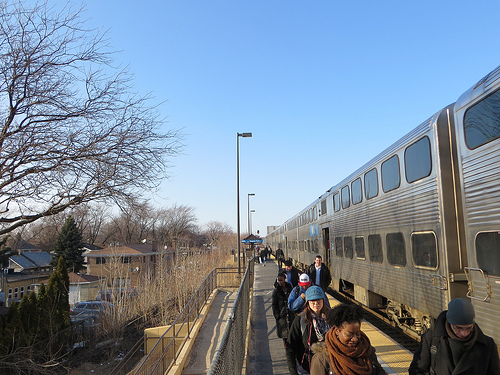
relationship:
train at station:
[254, 62, 498, 359] [186, 232, 413, 366]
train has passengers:
[254, 62, 498, 359] [258, 249, 498, 370]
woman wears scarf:
[309, 292, 388, 374] [313, 317, 375, 374]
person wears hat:
[401, 283, 499, 373] [440, 291, 477, 325]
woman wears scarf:
[309, 303, 386, 373] [315, 330, 378, 370]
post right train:
[229, 123, 257, 281] [254, 62, 498, 359]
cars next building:
[64, 299, 127, 334] [31, 269, 104, 310]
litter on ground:
[91, 338, 151, 373] [19, 302, 201, 373]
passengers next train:
[404, 294, 497, 375] [254, 62, 498, 359]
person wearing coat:
[408, 295, 500, 374] [406, 309, 497, 374]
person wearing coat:
[283, 281, 341, 373] [283, 310, 337, 369]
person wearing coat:
[271, 270, 298, 360] [268, 280, 298, 337]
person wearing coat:
[303, 254, 333, 301] [303, 260, 333, 292]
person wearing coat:
[276, 258, 303, 295] [280, 267, 302, 291]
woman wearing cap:
[289, 285, 331, 373] [304, 284, 324, 301]